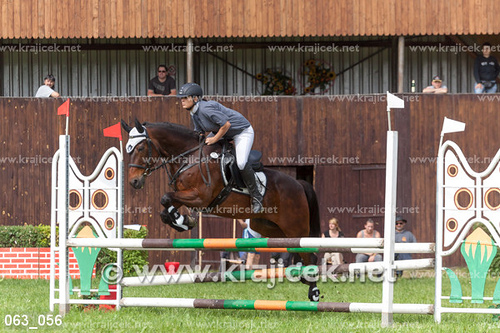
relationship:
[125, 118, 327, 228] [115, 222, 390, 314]
horse jumping a rail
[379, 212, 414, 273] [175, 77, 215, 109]
man has hat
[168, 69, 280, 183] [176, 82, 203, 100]
jockey wearing hat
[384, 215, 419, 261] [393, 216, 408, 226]
man wearing hat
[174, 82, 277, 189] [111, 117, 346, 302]
woman jumping horse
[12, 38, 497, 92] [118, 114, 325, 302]
spectators watching horse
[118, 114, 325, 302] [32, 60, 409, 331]
horse jumpimg competition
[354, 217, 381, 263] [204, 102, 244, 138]
man has vest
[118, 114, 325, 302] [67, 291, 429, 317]
horse jumping over hurdle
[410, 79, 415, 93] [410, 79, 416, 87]
beer of beer